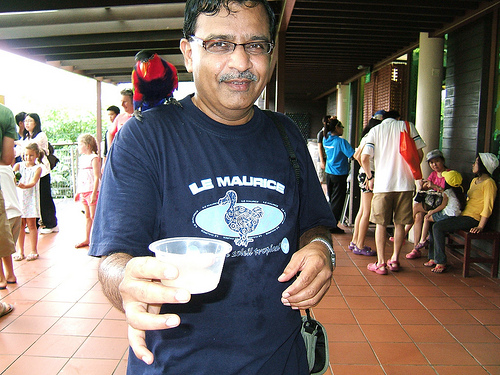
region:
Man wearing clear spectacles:
[173, 1, 277, 120]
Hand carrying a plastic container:
[96, 225, 235, 367]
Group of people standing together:
[0, 87, 145, 324]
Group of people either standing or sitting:
[313, 107, 498, 282]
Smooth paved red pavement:
[1, 211, 498, 372]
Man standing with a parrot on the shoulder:
[87, 1, 342, 373]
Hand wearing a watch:
[278, 230, 339, 315]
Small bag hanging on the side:
[276, 287, 335, 374]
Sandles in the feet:
[340, 238, 454, 278]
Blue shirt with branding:
[89, 90, 341, 372]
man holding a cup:
[81, 4, 366, 374]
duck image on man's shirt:
[214, 183, 276, 260]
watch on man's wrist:
[308, 232, 345, 273]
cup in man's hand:
[146, 218, 232, 305]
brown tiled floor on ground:
[342, 293, 489, 371]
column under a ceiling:
[407, 25, 457, 148]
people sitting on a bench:
[421, 133, 496, 290]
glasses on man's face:
[188, 31, 278, 61]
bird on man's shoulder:
[121, 42, 193, 114]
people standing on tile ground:
[3, 90, 72, 305]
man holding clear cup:
[55, 0, 415, 372]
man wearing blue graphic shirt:
[63, 48, 345, 373]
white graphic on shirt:
[105, 88, 322, 318]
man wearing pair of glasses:
[168, 23, 283, 68]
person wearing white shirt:
[355, 114, 429, 205]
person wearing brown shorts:
[361, 178, 422, 246]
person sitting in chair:
[407, 122, 497, 299]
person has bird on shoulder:
[85, 9, 351, 366]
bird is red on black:
[104, 45, 212, 122]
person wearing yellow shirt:
[438, 142, 498, 249]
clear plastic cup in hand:
[149, 236, 231, 292]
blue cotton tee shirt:
[90, 96, 335, 373]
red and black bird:
[127, 50, 179, 115]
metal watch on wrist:
[311, 235, 338, 270]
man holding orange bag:
[363, 108, 423, 272]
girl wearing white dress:
[15, 144, 45, 263]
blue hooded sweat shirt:
[321, 133, 353, 173]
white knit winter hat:
[480, 150, 498, 173]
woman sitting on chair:
[422, 152, 494, 273]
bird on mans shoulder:
[129, 50, 180, 120]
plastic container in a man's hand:
[145, 229, 246, 304]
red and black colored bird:
[124, 48, 187, 117]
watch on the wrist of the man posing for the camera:
[307, 231, 348, 283]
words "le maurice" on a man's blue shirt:
[181, 159, 292, 202]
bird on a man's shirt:
[214, 188, 270, 255]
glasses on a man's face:
[191, 24, 278, 61]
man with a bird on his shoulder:
[96, 2, 346, 374]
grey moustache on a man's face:
[216, 68, 267, 85]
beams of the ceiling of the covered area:
[0, 2, 486, 115]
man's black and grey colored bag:
[302, 302, 331, 374]